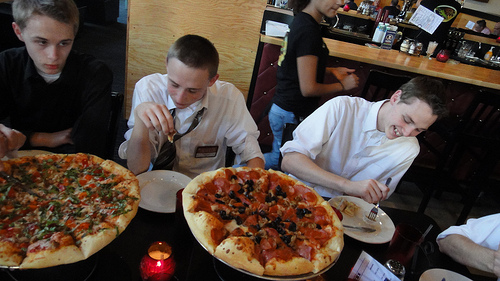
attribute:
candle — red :
[422, 47, 457, 69]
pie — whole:
[15, 147, 137, 274]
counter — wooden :
[261, 27, 498, 91]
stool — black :
[424, 85, 497, 227]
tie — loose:
[149, 106, 209, 171]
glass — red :
[378, 206, 435, 277]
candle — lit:
[128, 221, 191, 279]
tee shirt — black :
[0, 49, 158, 146]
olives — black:
[221, 179, 332, 244]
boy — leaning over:
[280, 71, 440, 227]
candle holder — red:
[138, 241, 176, 278]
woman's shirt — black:
[271, 27, 367, 104]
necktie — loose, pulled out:
[149, 106, 207, 172]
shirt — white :
[277, 96, 422, 210]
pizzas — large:
[1, 148, 140, 270]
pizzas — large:
[181, 159, 346, 279]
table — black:
[1, 161, 468, 279]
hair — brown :
[164, 33, 219, 83]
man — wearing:
[116, 31, 264, 176]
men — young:
[13, 0, 455, 227]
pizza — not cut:
[183, 166, 345, 274]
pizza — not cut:
[0, 147, 140, 266]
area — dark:
[0, 5, 128, 146]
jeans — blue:
[261, 107, 291, 173]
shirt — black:
[0, 47, 115, 165]